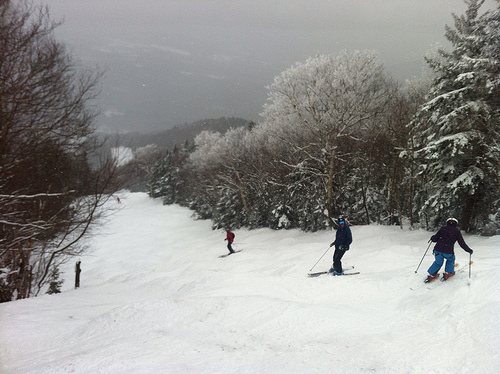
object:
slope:
[10, 186, 495, 372]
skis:
[410, 261, 474, 291]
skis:
[218, 249, 243, 258]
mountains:
[8, 0, 496, 184]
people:
[427, 217, 473, 280]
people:
[330, 218, 352, 275]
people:
[225, 227, 235, 255]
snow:
[1, 186, 498, 368]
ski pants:
[427, 250, 455, 275]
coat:
[226, 231, 233, 242]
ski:
[415, 217, 474, 284]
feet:
[333, 272, 343, 275]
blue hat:
[338, 215, 345, 228]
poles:
[310, 246, 331, 271]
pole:
[469, 253, 472, 277]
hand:
[469, 249, 473, 254]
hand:
[431, 235, 435, 240]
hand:
[330, 243, 334, 247]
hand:
[339, 245, 346, 250]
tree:
[417, 12, 496, 232]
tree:
[294, 51, 390, 230]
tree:
[9, 25, 91, 289]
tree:
[207, 128, 263, 224]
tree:
[170, 162, 192, 211]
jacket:
[432, 224, 469, 253]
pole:
[415, 240, 433, 274]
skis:
[308, 266, 360, 278]